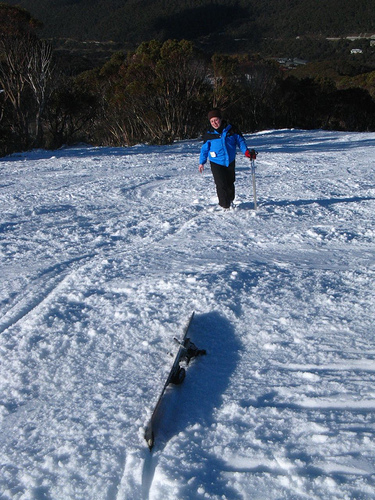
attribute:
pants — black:
[209, 157, 237, 209]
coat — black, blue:
[198, 123, 247, 166]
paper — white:
[208, 150, 216, 158]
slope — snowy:
[1, 124, 374, 497]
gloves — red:
[245, 151, 255, 157]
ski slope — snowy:
[2, 109, 373, 498]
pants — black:
[210, 158, 242, 216]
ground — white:
[8, 139, 372, 485]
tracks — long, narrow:
[0, 197, 193, 334]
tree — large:
[76, 31, 198, 157]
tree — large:
[203, 45, 279, 135]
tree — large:
[45, 66, 101, 153]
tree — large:
[2, 35, 57, 156]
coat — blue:
[200, 122, 252, 167]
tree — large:
[73, 46, 200, 125]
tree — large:
[96, 36, 225, 145]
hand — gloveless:
[196, 160, 206, 175]